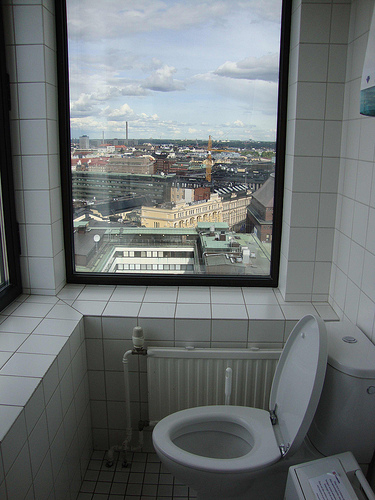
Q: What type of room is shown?
A: It is a bathroom.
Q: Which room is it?
A: It is a bathroom.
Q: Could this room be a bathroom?
A: Yes, it is a bathroom.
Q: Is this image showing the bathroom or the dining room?
A: It is showing the bathroom.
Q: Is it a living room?
A: No, it is a bathroom.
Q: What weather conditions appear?
A: It is cloudy.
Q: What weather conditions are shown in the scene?
A: It is cloudy.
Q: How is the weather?
A: It is cloudy.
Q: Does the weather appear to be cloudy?
A: Yes, it is cloudy.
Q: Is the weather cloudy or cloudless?
A: It is cloudy.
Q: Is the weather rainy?
A: No, it is cloudy.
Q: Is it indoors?
A: Yes, it is indoors.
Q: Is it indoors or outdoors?
A: It is indoors.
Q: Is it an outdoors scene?
A: No, it is indoors.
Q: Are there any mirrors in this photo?
A: No, there are no mirrors.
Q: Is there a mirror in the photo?
A: No, there are no mirrors.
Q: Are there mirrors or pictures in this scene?
A: No, there are no mirrors or pictures.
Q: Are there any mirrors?
A: No, there are no mirrors.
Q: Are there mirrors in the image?
A: No, there are no mirrors.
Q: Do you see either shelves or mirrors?
A: No, there are no mirrors or shelves.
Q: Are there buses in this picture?
A: No, there are no buses.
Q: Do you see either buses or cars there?
A: No, there are no buses or cars.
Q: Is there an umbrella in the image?
A: No, there are no umbrellas.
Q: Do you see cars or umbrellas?
A: No, there are no umbrellas or cars.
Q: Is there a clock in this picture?
A: No, there are no clocks.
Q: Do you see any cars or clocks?
A: No, there are no clocks or cars.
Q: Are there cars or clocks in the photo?
A: No, there are no clocks or cars.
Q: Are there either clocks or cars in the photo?
A: No, there are no clocks or cars.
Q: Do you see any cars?
A: No, there are no cars.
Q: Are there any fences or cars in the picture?
A: No, there are no cars or fences.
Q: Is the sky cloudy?
A: Yes, the sky is cloudy.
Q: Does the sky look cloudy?
A: Yes, the sky is cloudy.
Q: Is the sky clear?
A: No, the sky is cloudy.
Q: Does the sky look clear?
A: No, the sky is cloudy.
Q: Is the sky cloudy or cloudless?
A: The sky is cloudy.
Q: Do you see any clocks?
A: No, there are no clocks.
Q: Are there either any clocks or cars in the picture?
A: No, there are no clocks or cars.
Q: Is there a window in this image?
A: Yes, there is a window.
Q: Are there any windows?
A: Yes, there is a window.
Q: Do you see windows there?
A: Yes, there is a window.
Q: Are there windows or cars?
A: Yes, there is a window.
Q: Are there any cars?
A: No, there are no cars.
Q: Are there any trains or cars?
A: No, there are no cars or trains.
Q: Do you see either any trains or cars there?
A: No, there are no cars or trains.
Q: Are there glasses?
A: No, there are no glasses.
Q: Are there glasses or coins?
A: No, there are no glasses or coins.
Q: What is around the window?
A: The frame is around the window.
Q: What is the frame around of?
A: The frame is around the window.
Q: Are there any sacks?
A: No, there are no sacks.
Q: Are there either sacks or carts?
A: No, there are no sacks or carts.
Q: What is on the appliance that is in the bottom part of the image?
A: The pipe is on the radiator.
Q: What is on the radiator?
A: The pipe is on the radiator.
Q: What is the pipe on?
A: The pipe is on the radiator.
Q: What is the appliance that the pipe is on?
A: The appliance is a radiator.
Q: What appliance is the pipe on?
A: The pipe is on the radiator.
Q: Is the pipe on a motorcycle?
A: No, the pipe is on the radiator.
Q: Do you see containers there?
A: No, there are no containers.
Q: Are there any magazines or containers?
A: No, there are no containers or magazines.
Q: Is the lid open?
A: Yes, the lid is open.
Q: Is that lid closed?
A: No, the lid is open.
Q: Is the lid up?
A: Yes, the lid is up.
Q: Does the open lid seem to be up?
A: Yes, the lid is up.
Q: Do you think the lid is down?
A: No, the lid is up.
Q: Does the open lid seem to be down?
A: No, the lid is up.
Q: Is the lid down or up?
A: The lid is up.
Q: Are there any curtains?
A: No, there are no curtains.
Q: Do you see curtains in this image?
A: No, there are no curtains.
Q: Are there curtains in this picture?
A: No, there are no curtains.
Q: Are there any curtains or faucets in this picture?
A: No, there are no curtains or faucets.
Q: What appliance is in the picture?
A: The appliance is a radiator.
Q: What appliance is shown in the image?
A: The appliance is a radiator.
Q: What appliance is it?
A: The appliance is a radiator.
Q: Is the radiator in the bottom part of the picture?
A: Yes, the radiator is in the bottom of the image.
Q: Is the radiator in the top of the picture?
A: No, the radiator is in the bottom of the image.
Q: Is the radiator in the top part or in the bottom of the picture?
A: The radiator is in the bottom of the image.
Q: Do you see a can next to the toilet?
A: No, there is a radiator next to the toilet.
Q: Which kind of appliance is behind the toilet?
A: The appliance is a radiator.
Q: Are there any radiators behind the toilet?
A: Yes, there is a radiator behind the toilet.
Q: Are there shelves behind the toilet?
A: No, there is a radiator behind the toilet.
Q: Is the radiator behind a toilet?
A: Yes, the radiator is behind a toilet.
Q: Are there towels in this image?
A: No, there are no towels.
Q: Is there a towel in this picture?
A: No, there are no towels.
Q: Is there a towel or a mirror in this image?
A: No, there are no towels or mirrors.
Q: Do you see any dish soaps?
A: No, there are no dish soaps.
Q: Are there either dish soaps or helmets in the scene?
A: No, there are no dish soaps or helmets.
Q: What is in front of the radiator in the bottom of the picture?
A: The toilet is in front of the radiator.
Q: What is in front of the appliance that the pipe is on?
A: The toilet is in front of the radiator.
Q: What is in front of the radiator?
A: The toilet is in front of the radiator.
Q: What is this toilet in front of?
A: The toilet is in front of the radiator.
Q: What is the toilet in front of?
A: The toilet is in front of the radiator.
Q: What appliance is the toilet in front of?
A: The toilet is in front of the radiator.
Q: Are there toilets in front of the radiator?
A: Yes, there is a toilet in front of the radiator.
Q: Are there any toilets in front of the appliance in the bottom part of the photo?
A: Yes, there is a toilet in front of the radiator.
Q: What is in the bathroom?
A: The toilet is in the bathroom.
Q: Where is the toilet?
A: The toilet is in the bathroom.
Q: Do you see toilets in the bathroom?
A: Yes, there is a toilet in the bathroom.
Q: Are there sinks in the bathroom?
A: No, there is a toilet in the bathroom.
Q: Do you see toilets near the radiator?
A: Yes, there is a toilet near the radiator.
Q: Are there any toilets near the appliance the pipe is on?
A: Yes, there is a toilet near the radiator.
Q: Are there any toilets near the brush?
A: Yes, there is a toilet near the brush.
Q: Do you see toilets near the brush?
A: Yes, there is a toilet near the brush.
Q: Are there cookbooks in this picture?
A: No, there are no cookbooks.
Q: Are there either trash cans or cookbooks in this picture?
A: No, there are no cookbooks or trash cans.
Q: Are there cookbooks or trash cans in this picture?
A: No, there are no cookbooks or trash cans.